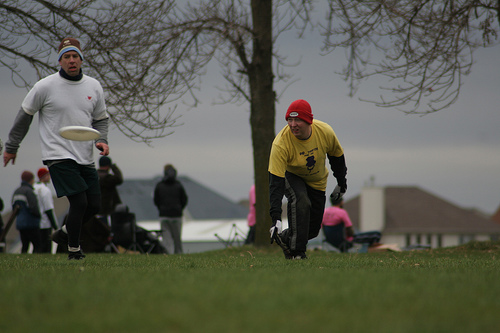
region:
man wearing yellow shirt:
[249, 100, 359, 264]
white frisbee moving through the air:
[58, 124, 102, 144]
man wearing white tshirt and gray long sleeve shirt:
[3, 26, 124, 253]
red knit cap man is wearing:
[280, 98, 317, 125]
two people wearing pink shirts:
[239, 171, 358, 250]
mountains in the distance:
[48, 166, 490, 234]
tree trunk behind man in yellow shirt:
[246, 3, 288, 243]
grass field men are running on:
[2, 238, 498, 330]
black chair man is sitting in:
[323, 219, 358, 251]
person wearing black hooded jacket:
[148, 158, 189, 250]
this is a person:
[4, 36, 113, 263]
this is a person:
[266, 100, 351, 260]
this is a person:
[153, 160, 191, 255]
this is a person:
[10, 168, 44, 253]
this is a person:
[323, 194, 368, 259]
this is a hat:
[55, 34, 87, 59]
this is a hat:
[282, 97, 319, 124]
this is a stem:
[237, 2, 285, 248]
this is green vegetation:
[6, 258, 118, 330]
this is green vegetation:
[277, 264, 489, 319]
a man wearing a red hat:
[258, 83, 353, 160]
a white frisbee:
[39, 108, 116, 145]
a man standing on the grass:
[231, 99, 383, 302]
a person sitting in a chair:
[312, 186, 389, 254]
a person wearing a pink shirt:
[314, 188, 377, 256]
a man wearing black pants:
[228, 96, 369, 273]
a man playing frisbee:
[15, 40, 143, 251]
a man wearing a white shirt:
[18, 30, 132, 231]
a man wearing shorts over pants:
[20, 41, 160, 311]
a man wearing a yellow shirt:
[235, 81, 375, 272]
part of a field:
[313, 304, 320, 313]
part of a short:
[75, 188, 80, 199]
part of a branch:
[419, 64, 426, 73]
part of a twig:
[413, 62, 430, 94]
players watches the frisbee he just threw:
[269, 98, 353, 260]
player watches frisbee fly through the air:
[3, 36, 112, 259]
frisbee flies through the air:
[57, 124, 102, 144]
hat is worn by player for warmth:
[284, 99, 318, 125]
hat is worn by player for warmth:
[54, 35, 86, 60]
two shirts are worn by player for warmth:
[267, 119, 349, 220]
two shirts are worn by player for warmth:
[3, 71, 108, 155]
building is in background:
[304, 181, 497, 251]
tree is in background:
[0, 0, 499, 242]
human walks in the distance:
[151, 164, 193, 256]